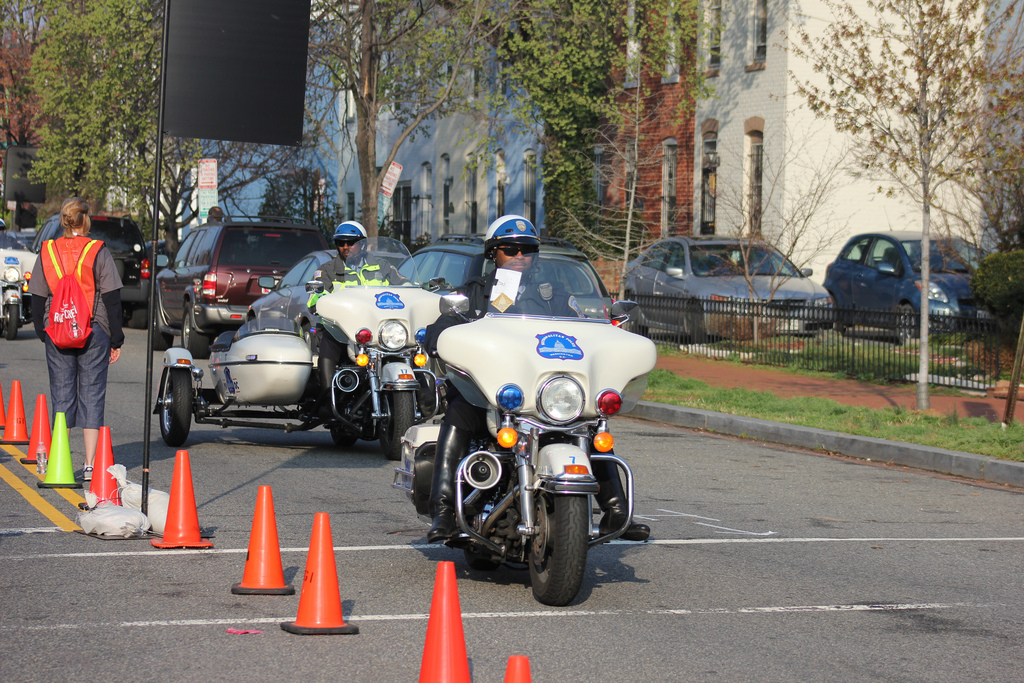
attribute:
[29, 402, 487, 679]
cones — security, orange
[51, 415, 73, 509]
cone — lime green, security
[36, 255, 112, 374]
backpack — red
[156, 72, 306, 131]
sign — black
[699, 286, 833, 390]
fence — black, metal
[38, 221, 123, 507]
woman — orange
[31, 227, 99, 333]
vest — securtiy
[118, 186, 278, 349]
suv — red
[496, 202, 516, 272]
helmet — white, blue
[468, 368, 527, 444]
light — blue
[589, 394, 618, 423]
light — red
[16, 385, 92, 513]
cone — bright, yellow, traffic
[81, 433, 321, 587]
cone — traffic, orange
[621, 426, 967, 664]
street — white lined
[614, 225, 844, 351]
car — parked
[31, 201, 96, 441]
woman — standing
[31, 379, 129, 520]
cone — neon green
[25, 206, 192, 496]
woman — safety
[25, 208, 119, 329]
vest — orange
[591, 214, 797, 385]
sedan — parked, silver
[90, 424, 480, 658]
cones — orange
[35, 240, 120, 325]
vest — safety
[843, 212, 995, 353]
car — blue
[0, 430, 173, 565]
lines — yellow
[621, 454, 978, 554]
lines — white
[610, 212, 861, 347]
car — silver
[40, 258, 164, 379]
backpack — red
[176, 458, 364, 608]
cones — orange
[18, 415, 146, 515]
cones — greenish yellow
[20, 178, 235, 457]
lady — young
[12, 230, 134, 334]
vest — safety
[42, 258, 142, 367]
backpack — red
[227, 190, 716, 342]
cars — parked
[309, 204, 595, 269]
helmets — blue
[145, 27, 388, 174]
sign — street, black, back